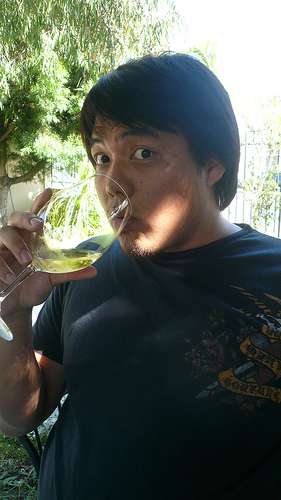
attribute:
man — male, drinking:
[0, 52, 281, 499]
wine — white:
[0, 173, 135, 343]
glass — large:
[0, 172, 136, 342]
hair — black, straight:
[78, 50, 240, 210]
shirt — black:
[30, 224, 280, 499]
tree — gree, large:
[0, 1, 184, 237]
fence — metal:
[220, 129, 278, 242]